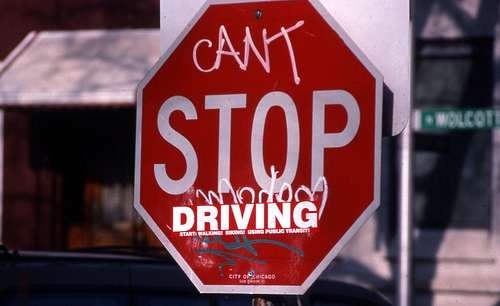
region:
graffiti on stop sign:
[190, 16, 314, 90]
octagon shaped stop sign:
[122, 1, 392, 298]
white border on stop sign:
[197, 282, 302, 297]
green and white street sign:
[408, 103, 496, 140]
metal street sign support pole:
[390, 111, 418, 304]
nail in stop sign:
[244, 6, 270, 23]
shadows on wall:
[13, 178, 132, 249]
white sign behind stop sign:
[161, 2, 414, 142]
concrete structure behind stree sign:
[415, 230, 497, 305]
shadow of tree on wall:
[410, 2, 492, 219]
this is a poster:
[125, 12, 385, 291]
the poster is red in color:
[302, 43, 344, 76]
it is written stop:
[148, 90, 373, 198]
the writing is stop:
[149, 83, 361, 198]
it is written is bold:
[154, 83, 360, 198]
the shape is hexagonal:
[126, 5, 386, 280]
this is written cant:
[185, 21, 310, 74]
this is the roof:
[45, 39, 106, 96]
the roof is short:
[63, 35, 118, 87]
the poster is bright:
[313, 44, 344, 74]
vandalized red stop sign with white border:
[133, 0, 383, 295]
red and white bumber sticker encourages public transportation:
[172, 200, 317, 235]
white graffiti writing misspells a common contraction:
[192, 20, 302, 84]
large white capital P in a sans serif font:
[310, 88, 360, 189]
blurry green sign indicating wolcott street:
[410, 108, 499, 129]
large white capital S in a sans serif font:
[152, 94, 197, 194]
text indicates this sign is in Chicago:
[228, 273, 275, 278]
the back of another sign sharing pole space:
[159, 0, 409, 135]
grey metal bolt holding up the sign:
[252, 9, 262, 18]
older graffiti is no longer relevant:
[195, 165, 327, 217]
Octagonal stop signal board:
[125, 3, 431, 298]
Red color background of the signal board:
[88, 9, 418, 304]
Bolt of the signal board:
[248, 8, 267, 23]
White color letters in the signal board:
[138, 35, 350, 235]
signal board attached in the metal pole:
[98, 2, 428, 301]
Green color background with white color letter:
[420, 103, 499, 145]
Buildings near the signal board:
[4, 8, 149, 303]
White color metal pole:
[383, 6, 419, 91]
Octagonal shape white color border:
[88, 0, 398, 305]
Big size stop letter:
[139, 90, 366, 228]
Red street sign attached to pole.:
[113, 25, 350, 303]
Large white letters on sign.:
[155, 95, 352, 187]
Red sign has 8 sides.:
[125, 18, 322, 247]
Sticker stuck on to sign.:
[163, 203, 327, 234]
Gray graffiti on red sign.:
[198, 236, 272, 263]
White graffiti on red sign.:
[199, 23, 319, 85]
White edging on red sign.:
[129, 30, 379, 300]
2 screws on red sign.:
[243, 5, 268, 290]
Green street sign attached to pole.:
[405, 98, 467, 150]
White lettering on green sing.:
[426, 99, 496, 151]